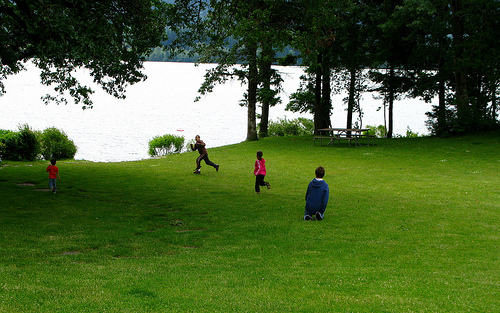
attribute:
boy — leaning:
[302, 161, 355, 230]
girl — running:
[235, 144, 282, 191]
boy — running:
[44, 150, 82, 191]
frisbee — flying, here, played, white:
[169, 116, 201, 150]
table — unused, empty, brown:
[312, 113, 373, 154]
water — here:
[124, 87, 232, 125]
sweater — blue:
[301, 182, 342, 216]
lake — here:
[98, 56, 325, 147]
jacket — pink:
[258, 163, 274, 175]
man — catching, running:
[171, 130, 217, 170]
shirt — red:
[49, 168, 74, 186]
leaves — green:
[68, 19, 120, 49]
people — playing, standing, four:
[42, 122, 328, 234]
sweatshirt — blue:
[312, 185, 332, 202]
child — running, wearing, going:
[243, 149, 290, 188]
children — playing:
[166, 130, 305, 208]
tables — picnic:
[305, 110, 396, 162]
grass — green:
[127, 209, 274, 302]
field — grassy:
[94, 171, 288, 275]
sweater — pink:
[256, 149, 284, 179]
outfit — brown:
[190, 132, 223, 173]